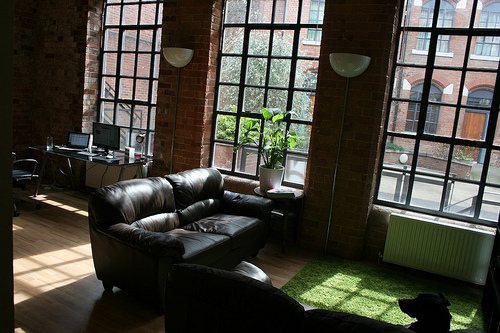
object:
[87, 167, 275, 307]
couch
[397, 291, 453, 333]
dog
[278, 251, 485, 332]
carpet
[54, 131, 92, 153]
laptop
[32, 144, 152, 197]
desk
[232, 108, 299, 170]
plant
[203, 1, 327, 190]
window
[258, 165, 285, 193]
pot